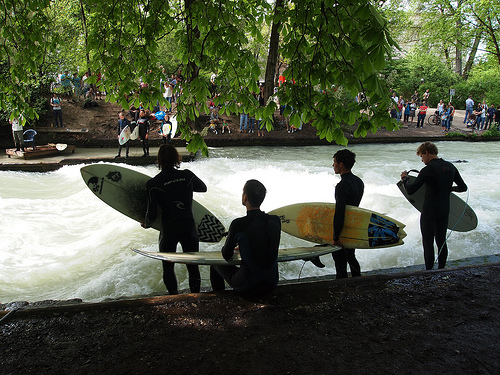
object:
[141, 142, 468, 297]
they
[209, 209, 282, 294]
wet suit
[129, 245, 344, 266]
surfboard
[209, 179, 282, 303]
man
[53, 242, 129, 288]
white foam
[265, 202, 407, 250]
surfboard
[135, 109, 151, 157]
person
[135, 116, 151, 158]
wetsuit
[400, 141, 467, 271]
man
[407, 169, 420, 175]
strap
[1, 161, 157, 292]
waves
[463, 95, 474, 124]
person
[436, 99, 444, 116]
person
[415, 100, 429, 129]
person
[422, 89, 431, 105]
person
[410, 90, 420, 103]
person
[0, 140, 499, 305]
water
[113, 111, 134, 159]
men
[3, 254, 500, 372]
ground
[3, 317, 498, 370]
dirt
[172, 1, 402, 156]
tree limbs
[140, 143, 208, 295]
man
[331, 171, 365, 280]
wetsuits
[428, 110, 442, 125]
bicycle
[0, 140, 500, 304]
river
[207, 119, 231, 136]
two children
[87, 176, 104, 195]
designs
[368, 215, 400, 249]
flower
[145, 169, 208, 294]
wetsuit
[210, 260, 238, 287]
lap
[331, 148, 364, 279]
man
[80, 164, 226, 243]
surfboard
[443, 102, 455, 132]
people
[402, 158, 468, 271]
wetsuit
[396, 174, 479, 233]
surfboard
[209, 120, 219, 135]
child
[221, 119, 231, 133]
child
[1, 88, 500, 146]
ground